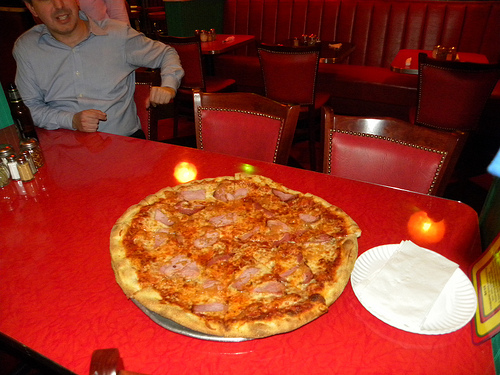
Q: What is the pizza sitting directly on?
A: Pan.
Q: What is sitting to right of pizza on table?
A: Plate.